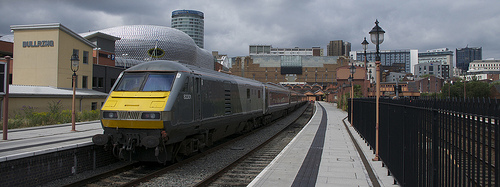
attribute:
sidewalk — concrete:
[241, 93, 403, 184]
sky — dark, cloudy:
[244, 6, 301, 38]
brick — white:
[345, 170, 362, 185]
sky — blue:
[222, 6, 256, 38]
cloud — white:
[344, 7, 497, 73]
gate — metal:
[347, 96, 487, 184]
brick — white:
[321, 99, 350, 177]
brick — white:
[330, 148, 346, 162]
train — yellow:
[92, 40, 309, 170]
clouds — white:
[242, 13, 285, 30]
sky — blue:
[389, 7, 499, 44]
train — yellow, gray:
[87, 47, 279, 157]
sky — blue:
[402, 0, 468, 38]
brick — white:
[330, 161, 357, 178]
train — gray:
[97, 57, 301, 161]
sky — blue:
[0, 0, 499, 59]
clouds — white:
[0, 0, 498, 61]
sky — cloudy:
[243, 17, 417, 52]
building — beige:
[26, 27, 113, 101]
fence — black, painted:
[350, 94, 500, 182]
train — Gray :
[95, 50, 335, 175]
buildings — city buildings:
[242, 37, 495, 98]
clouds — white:
[2, 0, 498, 70]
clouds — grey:
[4, 4, 483, 74]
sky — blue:
[3, 5, 484, 85]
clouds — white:
[3, 8, 91, 29]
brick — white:
[324, 157, 359, 175]